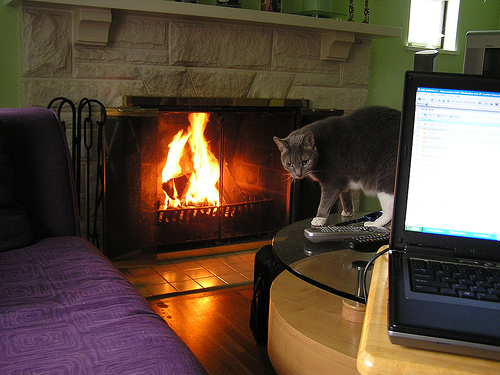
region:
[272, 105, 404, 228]
A gray and white cat.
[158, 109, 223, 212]
A bright orange fire.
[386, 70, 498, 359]
Black and silver laptop.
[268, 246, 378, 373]
Round wood table top.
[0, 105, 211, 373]
A purple colored couch.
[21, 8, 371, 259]
A stone wall fireplace.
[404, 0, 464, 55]
A small bright window.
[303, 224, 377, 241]
A silver remote control.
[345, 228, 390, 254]
A black remote control.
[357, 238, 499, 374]
A light wood table top.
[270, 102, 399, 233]
a grey can on a glass table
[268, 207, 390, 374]
a glass coffe table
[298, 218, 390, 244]
a silver colored remote control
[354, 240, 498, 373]
a light wood tv table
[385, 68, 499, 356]
a black and grey laptop on a tv table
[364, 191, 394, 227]
the white leg of a cat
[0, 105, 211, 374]
a purple couch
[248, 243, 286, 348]
a black suitcase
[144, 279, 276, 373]
a brown hardwood floor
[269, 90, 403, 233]
A grey and white cat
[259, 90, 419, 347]
A cat standing on top of a coffee table.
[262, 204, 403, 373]
A wooden coffee table with a glass top.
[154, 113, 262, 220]
An orange fire in the fireplace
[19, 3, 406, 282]
A beige stone fireplace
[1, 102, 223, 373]
A purple sofa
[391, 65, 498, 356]
A black laptop.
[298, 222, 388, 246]
A silver remote controller.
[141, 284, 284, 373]
Hardwood floors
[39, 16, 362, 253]
a fireplace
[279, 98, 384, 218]
a cat standing on a table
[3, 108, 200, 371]
a purple sofa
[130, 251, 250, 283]
tile in front of the fire place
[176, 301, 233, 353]
hard wood floor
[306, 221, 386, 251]
remotes on the table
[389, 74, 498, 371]
a laptop on a desk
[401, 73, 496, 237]
the screen of the laptop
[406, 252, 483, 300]
the keyboard of the laptop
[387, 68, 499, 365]
Open black laptop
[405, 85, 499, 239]
Open browser window on a screen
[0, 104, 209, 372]
Deep purple colored sofa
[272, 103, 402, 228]
Gray and white cat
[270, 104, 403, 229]
Cat standing on a glass table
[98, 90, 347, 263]
Wood burning fireplace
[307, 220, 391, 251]
Two remote controls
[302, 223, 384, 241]
Gray remote control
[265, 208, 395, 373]
Glass table top on a wood base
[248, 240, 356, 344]
Black suitcase behind a table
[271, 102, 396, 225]
white and gray cat on glass table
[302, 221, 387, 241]
large gray remote with gray buttons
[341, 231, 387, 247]
black remote with red power button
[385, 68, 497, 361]
open silver and black laptop computer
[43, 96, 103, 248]
black iron fireplace tool holder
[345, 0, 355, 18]
thin bronze candle stick on mantle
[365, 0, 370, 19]
skinny bronze candle stick on mantle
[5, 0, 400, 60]
long beige wooden mantle above fireplace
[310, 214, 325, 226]
furry white front left paw on cat